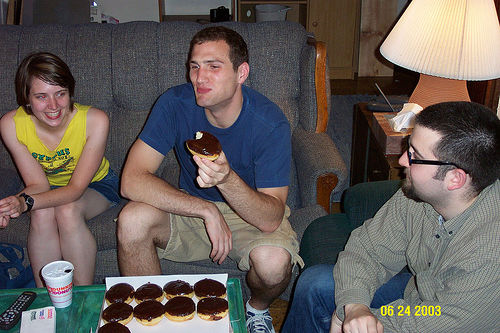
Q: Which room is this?
A: It is a living room.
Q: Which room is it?
A: It is a living room.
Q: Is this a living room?
A: Yes, it is a living room.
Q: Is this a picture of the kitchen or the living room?
A: It is showing the living room.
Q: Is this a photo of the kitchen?
A: No, the picture is showing the living room.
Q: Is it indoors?
A: Yes, it is indoors.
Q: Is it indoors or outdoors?
A: It is indoors.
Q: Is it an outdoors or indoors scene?
A: It is indoors.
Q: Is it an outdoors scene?
A: No, it is indoors.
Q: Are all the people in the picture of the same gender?
A: No, they are both male and female.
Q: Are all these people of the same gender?
A: No, they are both male and female.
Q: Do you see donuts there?
A: Yes, there is a donut.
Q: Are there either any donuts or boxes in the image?
A: Yes, there is a donut.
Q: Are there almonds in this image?
A: No, there are no almonds.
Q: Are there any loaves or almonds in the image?
A: No, there are no almonds or loaves.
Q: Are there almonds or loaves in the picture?
A: No, there are no almonds or loaves.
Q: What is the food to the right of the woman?
A: The food is a donut.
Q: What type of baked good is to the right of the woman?
A: The food is a donut.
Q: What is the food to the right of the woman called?
A: The food is a donut.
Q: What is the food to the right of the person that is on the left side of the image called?
A: The food is a donut.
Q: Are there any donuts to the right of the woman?
A: Yes, there is a donut to the right of the woman.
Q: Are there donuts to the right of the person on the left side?
A: Yes, there is a donut to the right of the woman.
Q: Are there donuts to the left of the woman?
A: No, the donut is to the right of the woman.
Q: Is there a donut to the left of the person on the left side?
A: No, the donut is to the right of the woman.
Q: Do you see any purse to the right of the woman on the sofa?
A: No, there is a donut to the right of the woman.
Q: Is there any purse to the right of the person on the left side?
A: No, there is a donut to the right of the woman.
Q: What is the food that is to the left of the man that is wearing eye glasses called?
A: The food is a donut.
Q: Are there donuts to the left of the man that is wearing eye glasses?
A: Yes, there is a donut to the left of the man.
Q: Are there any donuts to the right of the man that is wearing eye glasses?
A: No, the donut is to the left of the man.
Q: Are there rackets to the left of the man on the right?
A: No, there is a donut to the left of the man.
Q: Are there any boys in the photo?
A: No, there are no boys.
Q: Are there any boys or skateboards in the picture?
A: No, there are no boys or skateboards.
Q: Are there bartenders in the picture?
A: No, there are no bartenders.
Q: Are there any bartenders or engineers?
A: No, there are no bartenders or engineers.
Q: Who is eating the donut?
A: The man is eating the donut.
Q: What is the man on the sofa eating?
A: The man is eating a donut.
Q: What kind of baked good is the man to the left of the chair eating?
A: The man is eating a donut.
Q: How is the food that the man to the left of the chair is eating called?
A: The food is a donut.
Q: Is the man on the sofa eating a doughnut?
A: Yes, the man is eating a doughnut.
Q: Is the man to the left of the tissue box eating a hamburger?
A: No, the man is eating a doughnut.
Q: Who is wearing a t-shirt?
A: The man is wearing a t-shirt.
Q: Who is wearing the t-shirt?
A: The man is wearing a t-shirt.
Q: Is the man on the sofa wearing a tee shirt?
A: Yes, the man is wearing a tee shirt.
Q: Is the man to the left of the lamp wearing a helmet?
A: No, the man is wearing a tee shirt.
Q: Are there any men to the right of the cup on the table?
A: Yes, there is a man to the right of the cup.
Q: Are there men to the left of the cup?
A: No, the man is to the right of the cup.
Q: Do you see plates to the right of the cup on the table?
A: No, there is a man to the right of the cup.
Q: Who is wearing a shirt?
A: The man is wearing a shirt.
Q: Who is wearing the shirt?
A: The man is wearing a shirt.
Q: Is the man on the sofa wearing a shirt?
A: Yes, the man is wearing a shirt.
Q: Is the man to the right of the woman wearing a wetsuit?
A: No, the man is wearing a shirt.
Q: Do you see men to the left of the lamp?
A: Yes, there is a man to the left of the lamp.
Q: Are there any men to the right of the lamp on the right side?
A: No, the man is to the left of the lamp.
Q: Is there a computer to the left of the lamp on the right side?
A: No, there is a man to the left of the lamp.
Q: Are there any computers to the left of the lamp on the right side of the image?
A: No, there is a man to the left of the lamp.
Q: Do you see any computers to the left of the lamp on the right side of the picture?
A: No, there is a man to the left of the lamp.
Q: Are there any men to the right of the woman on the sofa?
A: Yes, there is a man to the right of the woman.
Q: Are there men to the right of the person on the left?
A: Yes, there is a man to the right of the woman.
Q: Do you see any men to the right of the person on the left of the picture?
A: Yes, there is a man to the right of the woman.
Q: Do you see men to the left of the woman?
A: No, the man is to the right of the woman.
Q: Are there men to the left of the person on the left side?
A: No, the man is to the right of the woman.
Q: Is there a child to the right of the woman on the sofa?
A: No, there is a man to the right of the woman.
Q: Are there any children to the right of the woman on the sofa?
A: No, there is a man to the right of the woman.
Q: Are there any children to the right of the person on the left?
A: No, there is a man to the right of the woman.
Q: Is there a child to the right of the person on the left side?
A: No, there is a man to the right of the woman.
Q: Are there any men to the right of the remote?
A: Yes, there is a man to the right of the remote.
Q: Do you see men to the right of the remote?
A: Yes, there is a man to the right of the remote.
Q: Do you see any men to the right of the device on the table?
A: Yes, there is a man to the right of the remote.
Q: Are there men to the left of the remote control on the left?
A: No, the man is to the right of the remote control.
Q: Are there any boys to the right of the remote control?
A: No, there is a man to the right of the remote control.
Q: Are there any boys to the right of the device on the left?
A: No, there is a man to the right of the remote control.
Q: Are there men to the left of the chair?
A: Yes, there is a man to the left of the chair.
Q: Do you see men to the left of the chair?
A: Yes, there is a man to the left of the chair.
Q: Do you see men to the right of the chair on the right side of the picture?
A: No, the man is to the left of the chair.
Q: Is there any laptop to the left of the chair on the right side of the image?
A: No, there is a man to the left of the chair.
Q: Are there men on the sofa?
A: Yes, there is a man on the sofa.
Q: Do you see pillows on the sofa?
A: No, there is a man on the sofa.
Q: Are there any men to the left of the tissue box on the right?
A: Yes, there is a man to the left of the tissue box.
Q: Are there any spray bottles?
A: No, there are no spray bottles.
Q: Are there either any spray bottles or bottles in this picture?
A: No, there are no spray bottles or bottles.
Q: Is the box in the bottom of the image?
A: Yes, the box is in the bottom of the image.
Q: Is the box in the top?
A: No, the box is in the bottom of the image.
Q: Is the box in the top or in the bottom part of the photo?
A: The box is in the bottom of the image.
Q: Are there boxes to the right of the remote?
A: Yes, there is a box to the right of the remote.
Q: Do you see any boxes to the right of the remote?
A: Yes, there is a box to the right of the remote.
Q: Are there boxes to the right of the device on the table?
A: Yes, there is a box to the right of the remote.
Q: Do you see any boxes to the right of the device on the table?
A: Yes, there is a box to the right of the remote.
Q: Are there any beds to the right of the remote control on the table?
A: No, there is a box to the right of the remote.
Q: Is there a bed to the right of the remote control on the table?
A: No, there is a box to the right of the remote.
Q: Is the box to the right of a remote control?
A: Yes, the box is to the right of a remote control.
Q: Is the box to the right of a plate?
A: No, the box is to the right of a remote control.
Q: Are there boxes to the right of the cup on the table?
A: Yes, there is a box to the right of the cup.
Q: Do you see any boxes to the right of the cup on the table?
A: Yes, there is a box to the right of the cup.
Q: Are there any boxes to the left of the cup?
A: No, the box is to the right of the cup.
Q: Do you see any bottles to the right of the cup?
A: No, there is a box to the right of the cup.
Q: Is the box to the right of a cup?
A: Yes, the box is to the right of a cup.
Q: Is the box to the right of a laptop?
A: No, the box is to the right of a cup.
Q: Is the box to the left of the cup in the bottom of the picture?
A: No, the box is to the right of the cup.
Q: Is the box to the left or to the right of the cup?
A: The box is to the right of the cup.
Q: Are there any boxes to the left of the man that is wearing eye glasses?
A: Yes, there is a box to the left of the man.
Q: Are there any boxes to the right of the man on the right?
A: No, the box is to the left of the man.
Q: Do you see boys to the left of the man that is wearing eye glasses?
A: No, there is a box to the left of the man.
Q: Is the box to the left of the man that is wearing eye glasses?
A: Yes, the box is to the left of the man.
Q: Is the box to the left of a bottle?
A: No, the box is to the left of the man.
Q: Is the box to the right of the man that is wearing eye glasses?
A: No, the box is to the left of the man.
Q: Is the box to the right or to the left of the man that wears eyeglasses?
A: The box is to the left of the man.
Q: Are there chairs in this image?
A: Yes, there is a chair.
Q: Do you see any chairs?
A: Yes, there is a chair.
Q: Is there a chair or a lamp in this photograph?
A: Yes, there is a chair.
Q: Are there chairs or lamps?
A: Yes, there is a chair.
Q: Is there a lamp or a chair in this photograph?
A: Yes, there is a chair.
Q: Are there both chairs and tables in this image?
A: Yes, there are both a chair and a table.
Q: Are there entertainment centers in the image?
A: No, there are no entertainment centers.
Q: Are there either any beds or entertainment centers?
A: No, there are no entertainment centers or beds.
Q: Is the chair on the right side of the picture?
A: Yes, the chair is on the right of the image.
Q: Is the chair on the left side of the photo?
A: No, the chair is on the right of the image.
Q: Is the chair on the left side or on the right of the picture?
A: The chair is on the right of the image.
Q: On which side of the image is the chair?
A: The chair is on the right of the image.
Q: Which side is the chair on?
A: The chair is on the right of the image.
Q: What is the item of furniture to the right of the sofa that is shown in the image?
A: The piece of furniture is a chair.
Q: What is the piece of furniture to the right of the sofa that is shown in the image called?
A: The piece of furniture is a chair.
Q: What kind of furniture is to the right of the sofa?
A: The piece of furniture is a chair.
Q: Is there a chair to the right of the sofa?
A: Yes, there is a chair to the right of the sofa.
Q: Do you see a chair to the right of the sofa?
A: Yes, there is a chair to the right of the sofa.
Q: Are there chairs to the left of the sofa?
A: No, the chair is to the right of the sofa.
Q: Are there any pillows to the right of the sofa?
A: No, there is a chair to the right of the sofa.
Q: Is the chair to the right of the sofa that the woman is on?
A: Yes, the chair is to the right of the sofa.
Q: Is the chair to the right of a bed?
A: No, the chair is to the right of the sofa.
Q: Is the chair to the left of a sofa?
A: No, the chair is to the right of a sofa.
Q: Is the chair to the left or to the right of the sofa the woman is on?
A: The chair is to the right of the sofa.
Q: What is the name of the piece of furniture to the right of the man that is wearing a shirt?
A: The piece of furniture is a chair.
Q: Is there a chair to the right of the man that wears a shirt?
A: Yes, there is a chair to the right of the man.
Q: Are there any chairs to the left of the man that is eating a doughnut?
A: No, the chair is to the right of the man.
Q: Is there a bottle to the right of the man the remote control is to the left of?
A: No, there is a chair to the right of the man.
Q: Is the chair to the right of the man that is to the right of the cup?
A: Yes, the chair is to the right of the man.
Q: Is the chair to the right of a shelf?
A: No, the chair is to the right of the man.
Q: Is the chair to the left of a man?
A: No, the chair is to the right of a man.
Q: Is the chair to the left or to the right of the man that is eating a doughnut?
A: The chair is to the right of the man.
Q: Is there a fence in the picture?
A: No, there are no fences.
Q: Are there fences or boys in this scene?
A: No, there are no fences or boys.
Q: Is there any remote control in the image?
A: Yes, there is a remote control.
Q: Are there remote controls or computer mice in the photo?
A: Yes, there is a remote control.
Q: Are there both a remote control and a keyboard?
A: No, there is a remote control but no keyboards.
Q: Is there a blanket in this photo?
A: No, there are no blankets.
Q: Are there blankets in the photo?
A: No, there are no blankets.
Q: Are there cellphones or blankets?
A: No, there are no blankets or cellphones.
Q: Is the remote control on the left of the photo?
A: Yes, the remote control is on the left of the image.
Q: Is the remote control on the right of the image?
A: No, the remote control is on the left of the image.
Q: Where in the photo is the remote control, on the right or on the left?
A: The remote control is on the left of the image.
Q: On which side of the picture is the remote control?
A: The remote control is on the left of the image.